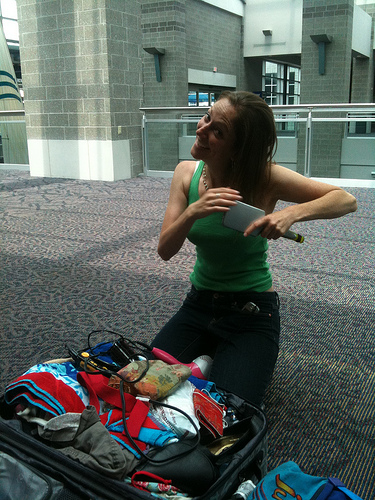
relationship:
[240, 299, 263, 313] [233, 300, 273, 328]
phone sticking out of pocket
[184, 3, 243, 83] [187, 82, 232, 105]
wall above doorway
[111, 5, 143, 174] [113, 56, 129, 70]
wall made of brick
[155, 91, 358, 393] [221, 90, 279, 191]
woman brushing hair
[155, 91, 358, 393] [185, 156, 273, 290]
woman wearing tank top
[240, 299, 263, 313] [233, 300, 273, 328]
cell phone located in pocket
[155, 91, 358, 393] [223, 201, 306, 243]
woman using brush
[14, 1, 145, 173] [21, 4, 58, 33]
column has bricks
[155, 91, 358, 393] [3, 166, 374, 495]
woman sitting on ground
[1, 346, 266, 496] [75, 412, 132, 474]
suitcase has clothes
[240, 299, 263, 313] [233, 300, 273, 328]
phone located in pocket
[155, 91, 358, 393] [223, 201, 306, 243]
woman holding brush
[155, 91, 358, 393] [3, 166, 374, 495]
woman kneeling on floor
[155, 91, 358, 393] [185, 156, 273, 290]
woman wearing shirt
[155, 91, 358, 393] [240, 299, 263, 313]
woman has cell phone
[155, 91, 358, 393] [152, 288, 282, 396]
woman wearing jeans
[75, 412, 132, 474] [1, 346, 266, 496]
clothes stored in suitcase